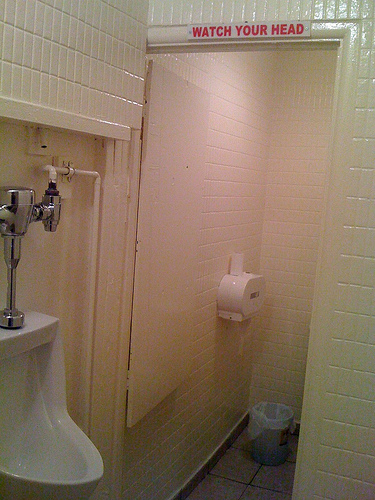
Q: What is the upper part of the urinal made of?
A: Chrome.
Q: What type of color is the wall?
A: White.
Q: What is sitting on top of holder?
A: Tissue.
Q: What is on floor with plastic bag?
A: Trash can.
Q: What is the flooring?
A: Tile.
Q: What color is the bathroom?
A: White.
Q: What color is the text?
A: Red.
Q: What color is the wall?
A: Beige.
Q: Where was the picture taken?
A: The bathroom.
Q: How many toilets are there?
A: One.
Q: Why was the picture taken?
A: To point out the low roof.